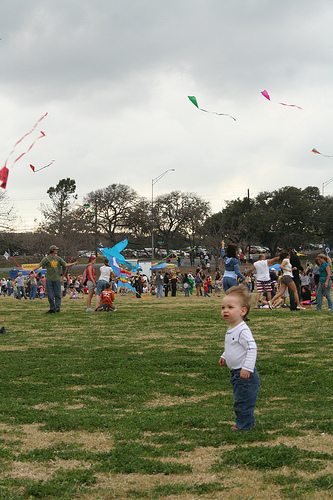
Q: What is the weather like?
A: It is cloudy.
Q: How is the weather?
A: It is cloudy.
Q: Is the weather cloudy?
A: Yes, it is cloudy.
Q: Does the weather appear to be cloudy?
A: Yes, it is cloudy.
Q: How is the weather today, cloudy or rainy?
A: It is cloudy.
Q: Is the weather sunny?
A: No, it is cloudy.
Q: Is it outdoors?
A: Yes, it is outdoors.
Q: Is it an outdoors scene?
A: Yes, it is outdoors.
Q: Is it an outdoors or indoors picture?
A: It is outdoors.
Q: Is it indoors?
A: No, it is outdoors.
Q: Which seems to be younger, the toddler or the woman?
A: The toddler is younger than the woman.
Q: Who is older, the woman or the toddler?
A: The woman is older than the toddler.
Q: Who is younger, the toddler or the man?
A: The toddler is younger than the man.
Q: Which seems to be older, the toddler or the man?
A: The man is older than the toddler.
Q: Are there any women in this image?
A: Yes, there is a woman.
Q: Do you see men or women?
A: Yes, there is a woman.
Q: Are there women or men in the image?
A: Yes, there is a woman.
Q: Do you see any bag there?
A: No, there are no bags.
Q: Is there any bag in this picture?
A: No, there are no bags.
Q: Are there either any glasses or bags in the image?
A: No, there are no bags or glasses.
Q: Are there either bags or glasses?
A: No, there are no bags or glasses.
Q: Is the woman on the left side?
A: Yes, the woman is on the left of the image.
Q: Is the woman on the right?
A: No, the woman is on the left of the image.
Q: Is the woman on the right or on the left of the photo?
A: The woman is on the left of the image.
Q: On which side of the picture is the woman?
A: The woman is on the left of the image.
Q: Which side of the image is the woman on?
A: The woman is on the left of the image.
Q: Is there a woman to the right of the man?
A: Yes, there is a woman to the right of the man.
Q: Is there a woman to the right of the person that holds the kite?
A: Yes, there is a woman to the right of the man.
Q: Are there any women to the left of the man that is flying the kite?
A: No, the woman is to the right of the man.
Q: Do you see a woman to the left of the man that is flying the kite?
A: No, the woman is to the right of the man.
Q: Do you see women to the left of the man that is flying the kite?
A: No, the woman is to the right of the man.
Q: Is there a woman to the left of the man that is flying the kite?
A: No, the woman is to the right of the man.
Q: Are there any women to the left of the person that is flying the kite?
A: No, the woman is to the right of the man.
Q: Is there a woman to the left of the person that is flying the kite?
A: No, the woman is to the right of the man.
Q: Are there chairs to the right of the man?
A: No, there is a woman to the right of the man.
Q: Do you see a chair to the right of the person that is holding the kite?
A: No, there is a woman to the right of the man.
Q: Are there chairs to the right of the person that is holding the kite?
A: No, there is a woman to the right of the man.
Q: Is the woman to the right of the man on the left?
A: Yes, the woman is to the right of the man.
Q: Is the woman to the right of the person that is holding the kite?
A: Yes, the woman is to the right of the man.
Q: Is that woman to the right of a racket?
A: No, the woman is to the right of the man.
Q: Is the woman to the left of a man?
A: No, the woman is to the right of a man.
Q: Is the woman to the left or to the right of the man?
A: The woman is to the right of the man.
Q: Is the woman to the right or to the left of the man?
A: The woman is to the right of the man.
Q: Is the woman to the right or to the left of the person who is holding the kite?
A: The woman is to the right of the man.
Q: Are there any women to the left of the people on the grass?
A: Yes, there is a woman to the left of the people.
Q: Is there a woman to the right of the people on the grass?
A: No, the woman is to the left of the people.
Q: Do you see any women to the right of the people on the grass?
A: No, the woman is to the left of the people.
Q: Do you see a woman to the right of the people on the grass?
A: No, the woman is to the left of the people.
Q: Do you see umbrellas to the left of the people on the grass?
A: No, there is a woman to the left of the people.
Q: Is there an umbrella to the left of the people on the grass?
A: No, there is a woman to the left of the people.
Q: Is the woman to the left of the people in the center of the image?
A: Yes, the woman is to the left of the people.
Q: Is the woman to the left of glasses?
A: No, the woman is to the left of the people.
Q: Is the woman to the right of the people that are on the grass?
A: No, the woman is to the left of the people.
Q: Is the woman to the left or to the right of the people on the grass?
A: The woman is to the left of the people.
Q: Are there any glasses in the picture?
A: No, there are no glasses.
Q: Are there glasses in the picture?
A: No, there are no glasses.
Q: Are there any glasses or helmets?
A: No, there are no glasses or helmets.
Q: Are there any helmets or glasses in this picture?
A: No, there are no glasses or helmets.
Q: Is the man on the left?
A: Yes, the man is on the left of the image.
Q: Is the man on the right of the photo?
A: No, the man is on the left of the image.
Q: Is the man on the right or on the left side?
A: The man is on the left of the image.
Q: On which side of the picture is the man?
A: The man is on the left of the image.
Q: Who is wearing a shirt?
A: The man is wearing a shirt.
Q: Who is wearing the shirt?
A: The man is wearing a shirt.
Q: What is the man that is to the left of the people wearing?
A: The man is wearing a shirt.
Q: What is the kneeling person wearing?
A: The man is wearing a shirt.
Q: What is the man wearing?
A: The man is wearing a shirt.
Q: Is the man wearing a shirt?
A: Yes, the man is wearing a shirt.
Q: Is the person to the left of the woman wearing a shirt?
A: Yes, the man is wearing a shirt.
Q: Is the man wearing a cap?
A: No, the man is wearing a shirt.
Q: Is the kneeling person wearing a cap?
A: No, the man is wearing a shirt.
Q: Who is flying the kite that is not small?
A: The man is flying the kite.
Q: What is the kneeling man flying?
A: The man is flying the kite.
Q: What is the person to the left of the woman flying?
A: The man is flying the kite.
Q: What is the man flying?
A: The man is flying the kite.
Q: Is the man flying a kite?
A: Yes, the man is flying a kite.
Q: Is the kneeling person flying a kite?
A: Yes, the man is flying a kite.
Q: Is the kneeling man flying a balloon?
A: No, the man is flying a kite.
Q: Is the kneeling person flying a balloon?
A: No, the man is flying a kite.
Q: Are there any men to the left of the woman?
A: Yes, there is a man to the left of the woman.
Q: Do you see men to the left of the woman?
A: Yes, there is a man to the left of the woman.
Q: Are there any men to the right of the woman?
A: No, the man is to the left of the woman.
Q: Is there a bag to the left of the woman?
A: No, there is a man to the left of the woman.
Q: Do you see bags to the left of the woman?
A: No, there is a man to the left of the woman.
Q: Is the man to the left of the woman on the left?
A: Yes, the man is to the left of the woman.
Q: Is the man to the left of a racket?
A: No, the man is to the left of the woman.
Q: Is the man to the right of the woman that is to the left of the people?
A: No, the man is to the left of the woman.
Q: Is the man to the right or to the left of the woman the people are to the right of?
A: The man is to the left of the woman.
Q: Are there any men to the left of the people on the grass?
A: Yes, there is a man to the left of the people.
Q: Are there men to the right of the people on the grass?
A: No, the man is to the left of the people.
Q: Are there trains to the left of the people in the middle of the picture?
A: No, there is a man to the left of the people.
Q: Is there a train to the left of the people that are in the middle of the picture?
A: No, there is a man to the left of the people.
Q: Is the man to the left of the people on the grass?
A: Yes, the man is to the left of the people.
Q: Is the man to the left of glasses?
A: No, the man is to the left of the people.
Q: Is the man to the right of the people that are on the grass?
A: No, the man is to the left of the people.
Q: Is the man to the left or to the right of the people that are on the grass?
A: The man is to the left of the people.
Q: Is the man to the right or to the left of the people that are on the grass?
A: The man is to the left of the people.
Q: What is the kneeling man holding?
A: The man is holding the kite.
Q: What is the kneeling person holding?
A: The man is holding the kite.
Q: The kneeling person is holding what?
A: The man is holding the kite.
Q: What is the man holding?
A: The man is holding the kite.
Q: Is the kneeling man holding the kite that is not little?
A: Yes, the man is holding the kite.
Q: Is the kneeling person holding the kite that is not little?
A: Yes, the man is holding the kite.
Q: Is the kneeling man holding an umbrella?
A: No, the man is holding the kite.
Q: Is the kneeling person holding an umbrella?
A: No, the man is holding the kite.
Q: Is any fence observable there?
A: No, there are no fences.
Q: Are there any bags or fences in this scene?
A: No, there are no fences or bags.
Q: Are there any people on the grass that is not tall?
A: Yes, there are people on the grass.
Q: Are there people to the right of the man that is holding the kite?
A: Yes, there are people to the right of the man.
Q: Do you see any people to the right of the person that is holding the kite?
A: Yes, there are people to the right of the man.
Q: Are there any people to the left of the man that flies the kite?
A: No, the people are to the right of the man.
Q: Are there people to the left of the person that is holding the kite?
A: No, the people are to the right of the man.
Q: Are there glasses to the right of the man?
A: No, there are people to the right of the man.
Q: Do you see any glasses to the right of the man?
A: No, there are people to the right of the man.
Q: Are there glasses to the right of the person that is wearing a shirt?
A: No, there are people to the right of the man.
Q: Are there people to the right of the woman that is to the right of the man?
A: Yes, there are people to the right of the woman.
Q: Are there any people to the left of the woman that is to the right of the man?
A: No, the people are to the right of the woman.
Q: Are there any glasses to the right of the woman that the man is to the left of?
A: No, there are people to the right of the woman.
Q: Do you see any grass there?
A: Yes, there is grass.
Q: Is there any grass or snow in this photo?
A: Yes, there is grass.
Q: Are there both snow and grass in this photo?
A: No, there is grass but no snow.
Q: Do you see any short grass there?
A: Yes, there is short grass.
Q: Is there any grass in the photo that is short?
A: Yes, there is grass that is short.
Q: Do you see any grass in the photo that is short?
A: Yes, there is grass that is short.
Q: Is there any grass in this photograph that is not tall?
A: Yes, there is short grass.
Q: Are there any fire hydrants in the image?
A: No, there are no fire hydrants.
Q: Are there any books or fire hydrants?
A: No, there are no fire hydrants or books.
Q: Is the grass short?
A: Yes, the grass is short.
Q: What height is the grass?
A: The grass is short.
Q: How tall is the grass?
A: The grass is short.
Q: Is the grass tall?
A: No, the grass is short.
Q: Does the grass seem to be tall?
A: No, the grass is short.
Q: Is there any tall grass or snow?
A: No, there is grass but it is short.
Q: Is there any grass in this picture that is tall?
A: No, there is grass but it is short.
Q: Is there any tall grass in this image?
A: No, there is grass but it is short.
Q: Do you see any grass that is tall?
A: No, there is grass but it is short.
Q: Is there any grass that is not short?
A: No, there is grass but it is short.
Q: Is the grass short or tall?
A: The grass is short.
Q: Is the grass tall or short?
A: The grass is short.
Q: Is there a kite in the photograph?
A: Yes, there is a kite.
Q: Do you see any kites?
A: Yes, there is a kite.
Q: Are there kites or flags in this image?
A: Yes, there is a kite.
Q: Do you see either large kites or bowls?
A: Yes, there is a large kite.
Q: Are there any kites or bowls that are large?
A: Yes, the kite is large.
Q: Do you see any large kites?
A: Yes, there is a large kite.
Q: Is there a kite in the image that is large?
A: Yes, there is a kite that is large.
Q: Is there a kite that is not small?
A: Yes, there is a large kite.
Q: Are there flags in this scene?
A: No, there are no flags.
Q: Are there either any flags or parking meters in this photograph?
A: No, there are no flags or parking meters.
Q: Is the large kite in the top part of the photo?
A: Yes, the kite is in the top of the image.